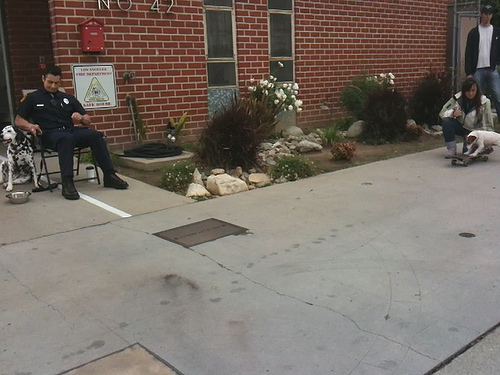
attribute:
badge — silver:
[61, 91, 73, 111]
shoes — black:
[54, 174, 134, 200]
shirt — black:
[28, 77, 162, 197]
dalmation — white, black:
[1, 114, 43, 195]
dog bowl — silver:
[8, 182, 33, 210]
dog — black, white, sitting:
[0, 120, 50, 199]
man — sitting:
[10, 66, 128, 200]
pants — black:
[35, 119, 130, 191]